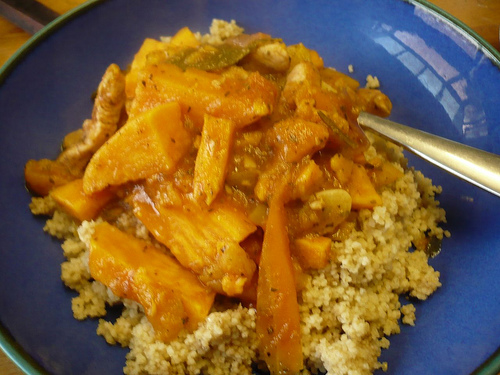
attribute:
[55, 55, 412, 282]
vegetable — orange 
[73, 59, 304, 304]
chicken — sauce covered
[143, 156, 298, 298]
meat — white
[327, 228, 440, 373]
grain — beige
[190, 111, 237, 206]
chicken — sauce covered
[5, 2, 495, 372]
plate — blue, round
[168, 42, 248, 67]
vetetable — green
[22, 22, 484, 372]
plate — blue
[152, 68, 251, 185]
piece chicken — sauced covered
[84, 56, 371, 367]
meat — white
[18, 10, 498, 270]
plate — blue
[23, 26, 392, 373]
vegetable dish — orange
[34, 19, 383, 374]
meat — orange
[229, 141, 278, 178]
sauce —  orange 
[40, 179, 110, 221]
chicken — sauced covered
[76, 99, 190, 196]
chicken — sauce covered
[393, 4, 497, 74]
trim — aqua colored